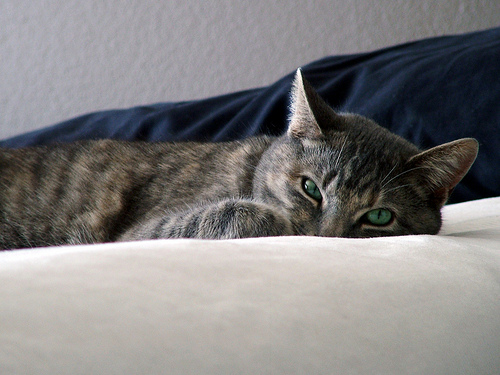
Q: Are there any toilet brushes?
A: No, there are no toilet brushes.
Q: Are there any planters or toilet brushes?
A: No, there are no toilet brushes or planters.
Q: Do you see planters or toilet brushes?
A: No, there are no toilet brushes or planters.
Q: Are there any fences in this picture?
A: No, there are no fences.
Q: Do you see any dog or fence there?
A: No, there are no fences or dogs.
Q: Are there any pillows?
A: Yes, there is a pillow.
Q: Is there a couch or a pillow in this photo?
A: Yes, there is a pillow.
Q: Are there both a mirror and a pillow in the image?
A: No, there is a pillow but no mirrors.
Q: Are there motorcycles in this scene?
A: No, there are no motorcycles.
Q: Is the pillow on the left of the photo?
A: No, the pillow is on the right of the image.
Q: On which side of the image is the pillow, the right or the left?
A: The pillow is on the right of the image.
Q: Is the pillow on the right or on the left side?
A: The pillow is on the right of the image.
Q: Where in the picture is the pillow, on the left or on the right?
A: The pillow is on the right of the image.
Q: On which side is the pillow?
A: The pillow is on the right of the image.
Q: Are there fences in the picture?
A: No, there are no fences.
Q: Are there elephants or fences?
A: No, there are no fences or elephants.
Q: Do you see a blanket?
A: Yes, there is a blanket.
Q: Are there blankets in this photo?
A: Yes, there is a blanket.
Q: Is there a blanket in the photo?
A: Yes, there is a blanket.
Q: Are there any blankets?
A: Yes, there is a blanket.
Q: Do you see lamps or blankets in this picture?
A: Yes, there is a blanket.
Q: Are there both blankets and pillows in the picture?
A: Yes, there are both a blanket and a pillow.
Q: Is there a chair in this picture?
A: No, there are no chairs.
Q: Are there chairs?
A: No, there are no chairs.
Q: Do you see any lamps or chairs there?
A: No, there are no chairs or lamps.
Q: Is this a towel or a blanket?
A: This is a blanket.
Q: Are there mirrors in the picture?
A: No, there are no mirrors.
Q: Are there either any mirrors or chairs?
A: No, there are no mirrors or chairs.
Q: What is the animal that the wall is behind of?
A: The animal is a cat.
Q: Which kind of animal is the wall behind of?
A: The wall is behind the cat.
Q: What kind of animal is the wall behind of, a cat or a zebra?
A: The wall is behind a cat.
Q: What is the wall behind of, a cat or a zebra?
A: The wall is behind a cat.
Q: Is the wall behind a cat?
A: Yes, the wall is behind a cat.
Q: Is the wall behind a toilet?
A: No, the wall is behind a cat.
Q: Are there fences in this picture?
A: No, there are no fences.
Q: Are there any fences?
A: No, there are no fences.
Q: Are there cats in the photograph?
A: Yes, there is a cat.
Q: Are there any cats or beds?
A: Yes, there is a cat.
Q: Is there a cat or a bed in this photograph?
A: Yes, there is a cat.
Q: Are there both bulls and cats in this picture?
A: No, there is a cat but no bulls.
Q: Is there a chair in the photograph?
A: No, there are no chairs.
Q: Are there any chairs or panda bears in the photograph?
A: No, there are no chairs or panda bears.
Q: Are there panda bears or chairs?
A: No, there are no chairs or panda bears.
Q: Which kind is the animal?
A: The animal is a cat.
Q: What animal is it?
A: The animal is a cat.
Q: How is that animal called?
A: That is a cat.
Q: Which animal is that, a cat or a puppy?
A: That is a cat.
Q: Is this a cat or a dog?
A: This is a cat.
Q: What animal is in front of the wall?
A: The cat is in front of the wall.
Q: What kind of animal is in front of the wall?
A: The animal is a cat.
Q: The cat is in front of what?
A: The cat is in front of the wall.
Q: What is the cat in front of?
A: The cat is in front of the wall.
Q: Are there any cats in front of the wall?
A: Yes, there is a cat in front of the wall.